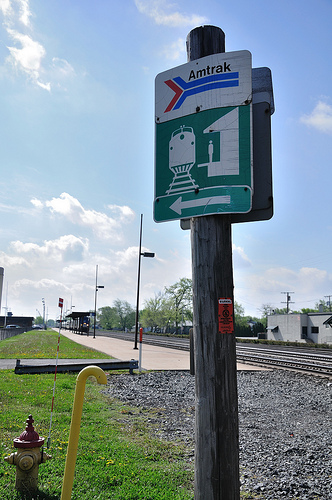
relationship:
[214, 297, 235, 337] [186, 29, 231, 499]
sticker sign on post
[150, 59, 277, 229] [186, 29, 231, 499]
train sign on post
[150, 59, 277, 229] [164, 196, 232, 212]
train sign has an arrow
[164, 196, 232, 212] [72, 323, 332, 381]
arrow pointing left of train track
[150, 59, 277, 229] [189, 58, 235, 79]
train sign has written on it amtrack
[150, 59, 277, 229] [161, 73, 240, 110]
train sign has amtrack logo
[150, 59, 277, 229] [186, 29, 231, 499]
train sign at top of post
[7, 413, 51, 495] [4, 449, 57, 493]
fire hydrant has bottom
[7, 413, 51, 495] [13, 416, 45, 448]
fire hydrant has top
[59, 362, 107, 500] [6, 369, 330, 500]
pipe juts out of ground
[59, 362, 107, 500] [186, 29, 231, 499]
pipe to right of post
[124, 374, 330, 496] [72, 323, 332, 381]
gravel-covered  area to bottom of train track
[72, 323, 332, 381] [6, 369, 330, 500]
train track on top of ground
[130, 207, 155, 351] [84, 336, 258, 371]
lamp post standing on platform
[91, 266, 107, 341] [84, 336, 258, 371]
lamp post standing on platform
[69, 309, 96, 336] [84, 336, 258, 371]
shelter at top of platform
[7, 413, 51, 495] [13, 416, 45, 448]
fire hydrant has a top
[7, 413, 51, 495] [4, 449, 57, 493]
fire hydrant has a bottom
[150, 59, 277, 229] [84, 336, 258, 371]
train sign in front of platform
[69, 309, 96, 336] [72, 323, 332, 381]
shelter beside train track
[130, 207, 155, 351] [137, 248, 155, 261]
lamp post has head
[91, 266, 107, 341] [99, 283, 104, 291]
lamp post has head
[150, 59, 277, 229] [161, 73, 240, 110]
train sign has printed on it an amtrack logo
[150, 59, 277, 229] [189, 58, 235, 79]
train sign has word amtrack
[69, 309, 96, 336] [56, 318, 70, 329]
shelter in front of shelter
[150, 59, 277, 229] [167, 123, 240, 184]
train sign has station logo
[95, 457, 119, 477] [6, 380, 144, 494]
dandelions are distributed in field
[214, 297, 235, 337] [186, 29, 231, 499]
sticker sign in middle of post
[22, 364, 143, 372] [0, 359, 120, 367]
rail guard in front of a road